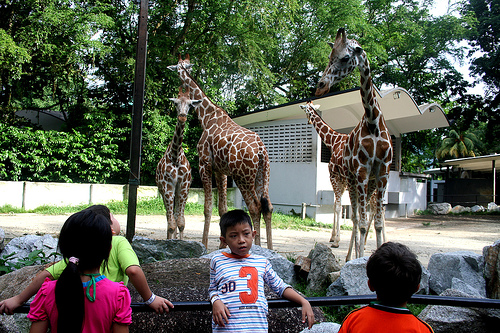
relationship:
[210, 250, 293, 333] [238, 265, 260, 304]
shirt has a number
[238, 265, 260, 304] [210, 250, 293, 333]
number on shirt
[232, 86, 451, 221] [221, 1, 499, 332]
building on right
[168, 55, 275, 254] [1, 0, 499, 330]
giraffe in zoo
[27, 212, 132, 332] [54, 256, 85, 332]
girl has a pony tail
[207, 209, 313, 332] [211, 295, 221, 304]
boy has a wristband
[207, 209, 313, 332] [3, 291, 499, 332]
child at fence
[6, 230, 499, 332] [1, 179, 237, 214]
rocks are in front of fence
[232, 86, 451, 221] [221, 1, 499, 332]
building on side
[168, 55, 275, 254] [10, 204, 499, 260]
giraffe on ground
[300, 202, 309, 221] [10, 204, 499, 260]
post on ground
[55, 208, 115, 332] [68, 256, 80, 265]
hair has a tie